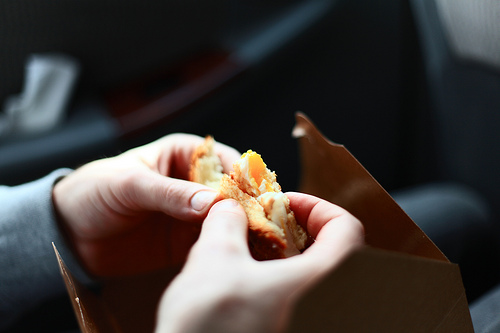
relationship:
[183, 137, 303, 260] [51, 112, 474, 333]
food came in bag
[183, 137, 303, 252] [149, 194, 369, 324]
food in hand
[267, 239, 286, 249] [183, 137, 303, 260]
seed on food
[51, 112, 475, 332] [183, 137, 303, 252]
bag of food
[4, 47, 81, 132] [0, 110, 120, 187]
cloth sticking out box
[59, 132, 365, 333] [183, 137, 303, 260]
hand holding food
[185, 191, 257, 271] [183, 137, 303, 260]
thumb supporting a food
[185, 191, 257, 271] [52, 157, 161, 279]
thumb attached to hand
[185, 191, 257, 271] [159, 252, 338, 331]
thumb attached to hand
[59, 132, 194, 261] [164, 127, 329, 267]
hand holding sandwich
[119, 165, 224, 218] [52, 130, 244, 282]
thumb attached to left hand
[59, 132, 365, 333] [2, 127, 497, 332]
hand belonging to person